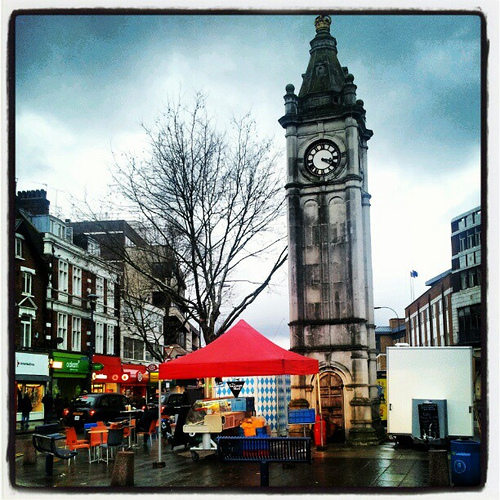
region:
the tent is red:
[162, 321, 337, 396]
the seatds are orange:
[67, 423, 111, 449]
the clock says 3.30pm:
[292, 132, 355, 180]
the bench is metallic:
[217, 428, 331, 478]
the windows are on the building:
[58, 264, 125, 354]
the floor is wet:
[348, 443, 421, 499]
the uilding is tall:
[259, 21, 385, 441]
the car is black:
[66, 384, 133, 424]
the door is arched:
[312, 368, 355, 438]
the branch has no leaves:
[125, 204, 270, 318]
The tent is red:
[157, 319, 319, 376]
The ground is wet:
[12, 440, 482, 492]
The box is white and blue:
[214, 375, 290, 435]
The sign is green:
[51, 349, 89, 377]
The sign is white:
[15, 351, 49, 373]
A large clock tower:
[279, 16, 384, 445]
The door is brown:
[315, 373, 344, 430]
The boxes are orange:
[240, 416, 265, 437]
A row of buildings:
[17, 190, 201, 421]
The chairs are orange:
[64, 423, 107, 448]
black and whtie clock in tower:
[310, 137, 345, 178]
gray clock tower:
[281, 40, 369, 301]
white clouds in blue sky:
[23, 21, 78, 68]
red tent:
[160, 318, 328, 399]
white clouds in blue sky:
[23, 57, 61, 121]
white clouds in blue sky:
[63, 117, 94, 161]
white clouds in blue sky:
[76, 31, 137, 73]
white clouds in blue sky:
[154, 48, 254, 86]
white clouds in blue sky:
[364, 23, 449, 103]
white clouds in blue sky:
[393, 137, 455, 202]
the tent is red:
[120, 313, 383, 442]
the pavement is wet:
[338, 431, 424, 495]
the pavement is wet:
[159, 449, 283, 499]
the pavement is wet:
[100, 440, 245, 490]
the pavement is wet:
[205, 425, 355, 492]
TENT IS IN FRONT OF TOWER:
[157, 315, 327, 474]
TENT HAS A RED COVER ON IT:
[163, 320, 323, 377]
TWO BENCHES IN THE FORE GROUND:
[29, 434, 308, 481]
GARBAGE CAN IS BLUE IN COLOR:
[448, 437, 485, 487]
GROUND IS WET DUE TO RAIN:
[79, 442, 425, 486]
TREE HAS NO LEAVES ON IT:
[119, 105, 273, 352]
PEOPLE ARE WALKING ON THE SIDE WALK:
[20, 388, 67, 422]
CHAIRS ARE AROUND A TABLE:
[71, 413, 133, 467]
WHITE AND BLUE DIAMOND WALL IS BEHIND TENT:
[216, 373, 291, 430]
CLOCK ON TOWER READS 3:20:
[297, 130, 351, 188]